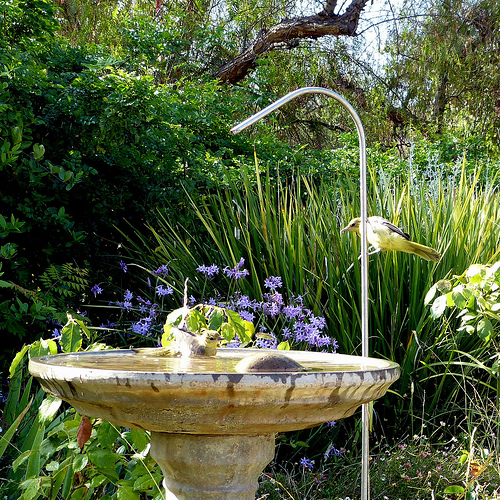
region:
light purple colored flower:
[316, 335, 327, 345]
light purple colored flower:
[223, 338, 240, 348]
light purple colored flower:
[292, 325, 303, 341]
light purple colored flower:
[287, 317, 302, 328]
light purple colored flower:
[280, 298, 301, 320]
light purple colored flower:
[205, 261, 220, 271]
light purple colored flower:
[192, 262, 205, 272]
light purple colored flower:
[122, 285, 129, 302]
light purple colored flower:
[130, 322, 143, 333]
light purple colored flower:
[141, 313, 154, 323]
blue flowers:
[282, 300, 332, 347]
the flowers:
[271, 307, 329, 344]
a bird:
[338, 215, 355, 234]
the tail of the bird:
[411, 238, 439, 266]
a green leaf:
[52, 318, 87, 347]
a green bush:
[8, 140, 86, 192]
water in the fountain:
[115, 355, 192, 372]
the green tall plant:
[377, 273, 417, 324]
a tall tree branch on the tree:
[420, 91, 453, 125]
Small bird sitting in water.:
[163, 328, 238, 358]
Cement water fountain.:
[23, 347, 406, 496]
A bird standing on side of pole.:
[339, 216, 438, 272]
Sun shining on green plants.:
[430, 136, 495, 343]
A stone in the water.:
[236, 348, 304, 371]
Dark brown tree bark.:
[213, 0, 377, 82]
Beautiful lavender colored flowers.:
[105, 261, 329, 343]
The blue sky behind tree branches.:
[300, 0, 440, 77]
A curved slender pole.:
[222, 86, 413, 496]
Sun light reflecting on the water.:
[63, 354, 231, 376]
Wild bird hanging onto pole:
[340, 215, 440, 263]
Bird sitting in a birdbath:
[165, 325, 228, 359]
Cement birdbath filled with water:
[25, 340, 405, 499]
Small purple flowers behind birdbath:
[46, 261, 353, 482]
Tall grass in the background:
[110, 144, 494, 453]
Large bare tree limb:
[205, 0, 375, 82]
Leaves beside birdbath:
[0, 320, 166, 499]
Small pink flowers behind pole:
[276, 419, 497, 499]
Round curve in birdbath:
[234, 350, 309, 375]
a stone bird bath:
[26, 346, 403, 499]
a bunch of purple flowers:
[49, 258, 341, 356]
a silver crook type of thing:
[232, 82, 372, 499]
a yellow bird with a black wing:
[337, 213, 442, 266]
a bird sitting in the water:
[168, 321, 223, 359]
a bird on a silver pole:
[339, 214, 439, 264]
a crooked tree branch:
[191, 2, 377, 89]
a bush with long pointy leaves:
[118, 142, 499, 437]